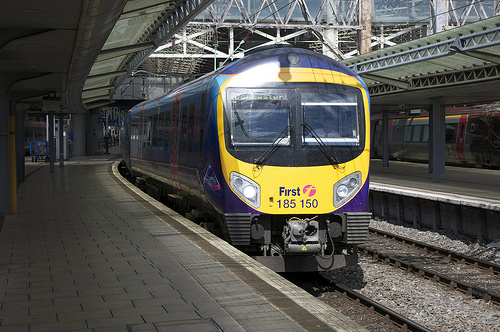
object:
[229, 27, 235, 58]
beams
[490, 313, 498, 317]
gravel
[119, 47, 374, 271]
train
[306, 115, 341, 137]
motorman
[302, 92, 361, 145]
window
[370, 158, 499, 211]
platform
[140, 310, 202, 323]
bricks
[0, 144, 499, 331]
ground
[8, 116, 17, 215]
pole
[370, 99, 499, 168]
train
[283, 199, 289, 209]
id number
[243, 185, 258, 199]
light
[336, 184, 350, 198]
light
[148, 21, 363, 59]
infrastructure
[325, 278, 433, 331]
track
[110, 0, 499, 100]
ceiling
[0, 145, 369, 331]
platform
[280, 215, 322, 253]
motor